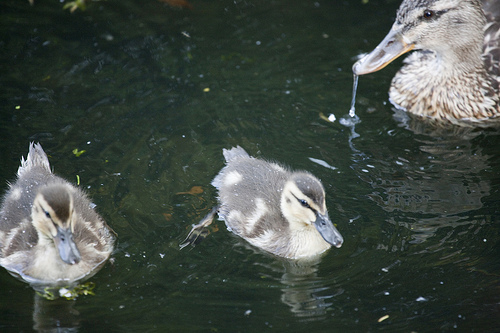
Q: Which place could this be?
A: It is a lake.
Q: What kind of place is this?
A: It is a lake.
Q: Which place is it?
A: It is a lake.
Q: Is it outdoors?
A: Yes, it is outdoors.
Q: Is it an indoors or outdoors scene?
A: It is outdoors.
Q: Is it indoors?
A: No, it is outdoors.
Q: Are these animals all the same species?
A: Yes, all the animals are ducks.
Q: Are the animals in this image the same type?
A: Yes, all the animals are ducks.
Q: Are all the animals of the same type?
A: Yes, all the animals are ducks.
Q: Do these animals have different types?
A: No, all the animals are ducks.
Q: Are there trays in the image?
A: No, there are no trays.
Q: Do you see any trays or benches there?
A: No, there are no trays or benches.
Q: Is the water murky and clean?
A: No, the water is murky but dirty.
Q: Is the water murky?
A: Yes, the water is murky.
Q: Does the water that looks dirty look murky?
A: Yes, the water is murky.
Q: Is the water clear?
A: No, the water is murky.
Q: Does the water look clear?
A: No, the water is murky.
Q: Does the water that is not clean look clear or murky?
A: The water is murky.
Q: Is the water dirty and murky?
A: Yes, the water is dirty and murky.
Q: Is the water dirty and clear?
A: No, the water is dirty but murky.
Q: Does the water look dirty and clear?
A: No, the water is dirty but murky.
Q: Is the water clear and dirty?
A: No, the water is dirty but murky.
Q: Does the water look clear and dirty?
A: No, the water is dirty but murky.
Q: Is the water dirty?
A: Yes, the water is dirty.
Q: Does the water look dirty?
A: Yes, the water is dirty.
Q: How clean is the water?
A: The water is dirty.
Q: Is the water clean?
A: No, the water is dirty.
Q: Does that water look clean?
A: No, the water is dirty.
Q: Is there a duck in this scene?
A: Yes, there are ducks.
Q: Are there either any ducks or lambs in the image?
A: Yes, there are ducks.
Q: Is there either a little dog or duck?
A: Yes, there are little ducks.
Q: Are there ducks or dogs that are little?
A: Yes, the ducks are little.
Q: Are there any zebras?
A: No, there are no zebras.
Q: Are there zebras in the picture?
A: No, there are no zebras.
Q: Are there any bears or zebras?
A: No, there are no zebras or bears.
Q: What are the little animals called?
A: The animals are ducks.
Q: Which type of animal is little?
A: The animal is ducks.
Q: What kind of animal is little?
A: The animal is ducks.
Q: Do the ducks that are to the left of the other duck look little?
A: Yes, the ducks are little.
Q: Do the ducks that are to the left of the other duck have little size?
A: Yes, the ducks are little.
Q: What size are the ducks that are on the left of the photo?
A: The ducks are little.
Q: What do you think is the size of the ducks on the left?
A: The ducks are little.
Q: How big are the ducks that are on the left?
A: The ducks are little.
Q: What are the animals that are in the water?
A: The animals are ducks.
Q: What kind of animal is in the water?
A: The animals are ducks.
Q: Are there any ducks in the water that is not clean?
A: Yes, there are ducks in the water.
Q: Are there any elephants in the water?
A: No, there are ducks in the water.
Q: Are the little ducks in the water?
A: Yes, the ducks are in the water.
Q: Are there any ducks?
A: Yes, there is a duck.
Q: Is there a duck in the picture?
A: Yes, there is a duck.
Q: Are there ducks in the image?
A: Yes, there is a duck.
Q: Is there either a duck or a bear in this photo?
A: Yes, there is a duck.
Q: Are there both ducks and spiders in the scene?
A: No, there is a duck but no spiders.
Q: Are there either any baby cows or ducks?
A: Yes, there is a baby duck.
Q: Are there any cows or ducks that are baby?
A: Yes, the duck is a baby.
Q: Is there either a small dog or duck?
A: Yes, there is a small duck.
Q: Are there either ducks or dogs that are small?
A: Yes, the duck is small.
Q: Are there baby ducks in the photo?
A: Yes, there is a baby duck.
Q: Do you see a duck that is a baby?
A: Yes, there is a duck that is a baby.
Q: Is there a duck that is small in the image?
A: Yes, there is a small duck.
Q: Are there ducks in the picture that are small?
A: Yes, there is a duck that is small.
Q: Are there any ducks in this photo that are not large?
A: Yes, there is a small duck.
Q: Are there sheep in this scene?
A: No, there are no sheep.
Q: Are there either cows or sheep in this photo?
A: No, there are no sheep or cows.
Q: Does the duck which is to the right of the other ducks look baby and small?
A: Yes, the duck is a baby and small.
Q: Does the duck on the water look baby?
A: Yes, the duck is a baby.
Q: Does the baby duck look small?
A: Yes, the duck is small.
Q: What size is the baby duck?
A: The duck is small.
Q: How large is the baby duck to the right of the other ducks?
A: The duck is small.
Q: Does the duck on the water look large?
A: No, the duck is small.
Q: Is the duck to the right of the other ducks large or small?
A: The duck is small.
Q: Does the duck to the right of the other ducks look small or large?
A: The duck is small.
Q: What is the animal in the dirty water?
A: The animal is a duck.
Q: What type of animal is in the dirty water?
A: The animal is a duck.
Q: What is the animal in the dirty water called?
A: The animal is a duck.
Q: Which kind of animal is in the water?
A: The animal is a duck.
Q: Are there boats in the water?
A: No, there is a duck in the water.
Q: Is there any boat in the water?
A: No, there is a duck in the water.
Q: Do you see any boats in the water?
A: No, there is a duck in the water.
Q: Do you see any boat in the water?
A: No, there is a duck in the water.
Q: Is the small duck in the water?
A: Yes, the duck is in the water.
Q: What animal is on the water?
A: The duck is on the water.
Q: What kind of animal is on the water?
A: The animal is a duck.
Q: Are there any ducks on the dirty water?
A: Yes, there is a duck on the water.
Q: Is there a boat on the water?
A: No, there is a duck on the water.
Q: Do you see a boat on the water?
A: No, there is a duck on the water.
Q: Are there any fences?
A: No, there are no fences.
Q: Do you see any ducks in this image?
A: Yes, there is a duck.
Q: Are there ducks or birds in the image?
A: Yes, there is a duck.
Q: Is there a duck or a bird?
A: Yes, there is a duck.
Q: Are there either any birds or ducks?
A: Yes, there is a duck.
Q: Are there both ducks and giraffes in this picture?
A: No, there is a duck but no giraffes.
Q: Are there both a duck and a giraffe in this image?
A: No, there is a duck but no giraffes.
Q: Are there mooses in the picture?
A: No, there are no mooses.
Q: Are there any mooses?
A: No, there are no mooses.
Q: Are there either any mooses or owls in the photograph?
A: No, there are no mooses or owls.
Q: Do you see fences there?
A: No, there are no fences.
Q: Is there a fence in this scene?
A: No, there are no fences.